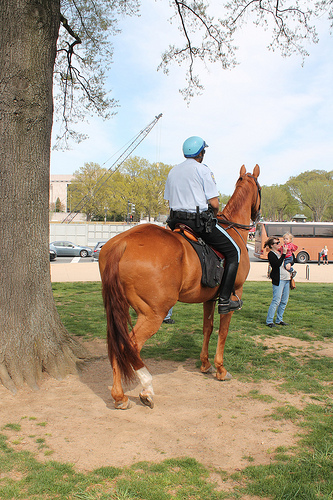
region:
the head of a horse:
[224, 170, 281, 214]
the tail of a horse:
[102, 248, 164, 385]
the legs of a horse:
[114, 257, 209, 422]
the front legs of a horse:
[177, 258, 266, 377]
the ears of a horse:
[226, 161, 268, 189]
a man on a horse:
[112, 66, 311, 342]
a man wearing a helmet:
[165, 136, 221, 175]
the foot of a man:
[197, 268, 299, 321]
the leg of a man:
[211, 226, 261, 310]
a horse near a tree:
[19, 145, 319, 413]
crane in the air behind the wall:
[52, 111, 161, 217]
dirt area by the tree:
[73, 361, 224, 453]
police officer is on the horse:
[169, 123, 246, 313]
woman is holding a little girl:
[262, 229, 296, 313]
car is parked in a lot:
[52, 235, 88, 260]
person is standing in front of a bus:
[313, 241, 330, 266]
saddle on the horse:
[177, 219, 227, 284]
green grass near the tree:
[57, 279, 96, 328]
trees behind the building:
[274, 178, 331, 208]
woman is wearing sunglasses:
[267, 238, 284, 251]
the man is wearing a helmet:
[172, 135, 283, 191]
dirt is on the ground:
[64, 393, 284, 485]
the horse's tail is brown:
[76, 254, 221, 466]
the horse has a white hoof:
[96, 357, 221, 449]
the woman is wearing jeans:
[264, 287, 326, 362]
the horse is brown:
[124, 228, 230, 342]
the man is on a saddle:
[154, 209, 297, 326]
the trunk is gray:
[5, 114, 102, 323]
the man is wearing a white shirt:
[155, 156, 286, 259]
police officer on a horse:
[100, 135, 261, 412]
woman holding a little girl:
[264, 232, 298, 327]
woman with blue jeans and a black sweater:
[264, 236, 288, 328]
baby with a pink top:
[277, 234, 296, 276]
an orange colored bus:
[253, 221, 331, 259]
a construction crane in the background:
[64, 111, 164, 219]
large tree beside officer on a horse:
[2, 2, 328, 378]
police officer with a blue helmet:
[166, 134, 243, 313]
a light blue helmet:
[184, 138, 209, 155]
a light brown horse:
[101, 165, 262, 409]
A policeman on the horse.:
[158, 117, 230, 264]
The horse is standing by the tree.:
[123, 182, 279, 332]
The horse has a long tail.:
[91, 269, 135, 376]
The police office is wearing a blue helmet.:
[173, 129, 214, 159]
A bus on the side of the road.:
[260, 220, 332, 260]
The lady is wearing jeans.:
[267, 280, 296, 322]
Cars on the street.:
[53, 229, 116, 257]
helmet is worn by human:
[182, 135, 209, 156]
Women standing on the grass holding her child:
[265, 233, 296, 327]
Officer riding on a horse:
[100, 136, 262, 407]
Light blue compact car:
[50, 241, 91, 257]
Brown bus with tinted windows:
[254, 222, 332, 262]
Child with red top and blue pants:
[280, 232, 298, 278]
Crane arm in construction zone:
[60, 111, 166, 225]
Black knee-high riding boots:
[217, 259, 244, 311]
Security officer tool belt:
[165, 206, 220, 233]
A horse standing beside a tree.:
[18, 125, 294, 409]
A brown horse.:
[80, 169, 273, 398]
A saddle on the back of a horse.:
[159, 219, 225, 275]